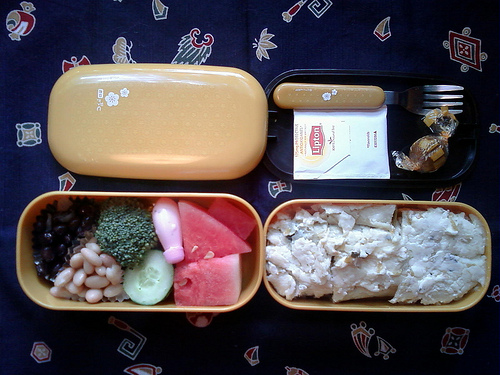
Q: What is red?
A: Watermelon.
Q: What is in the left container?
A: Food.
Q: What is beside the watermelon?
A: Beans.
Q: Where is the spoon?
A: No spoon.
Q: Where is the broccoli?
A: In the container.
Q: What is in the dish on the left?
A: Fruits and veggies.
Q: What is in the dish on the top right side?
A: A fork, tea bag and a piece of candy.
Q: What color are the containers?
A: Tan.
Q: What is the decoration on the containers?
A: White flowers.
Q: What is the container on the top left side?
A: A cover.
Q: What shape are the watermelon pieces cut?
A: Triangles.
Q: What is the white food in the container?
A: A type of dip.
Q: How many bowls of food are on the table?
A: Two.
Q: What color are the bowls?
A: Tan.